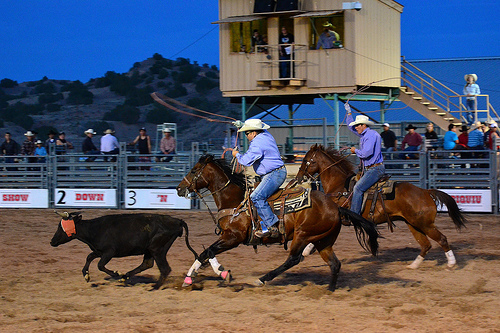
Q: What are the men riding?
A: Horses.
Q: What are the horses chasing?
A: A cow.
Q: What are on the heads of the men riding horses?
A: Cowboy hats.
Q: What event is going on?
A: Rodeo.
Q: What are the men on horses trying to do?
A: Rope a cow.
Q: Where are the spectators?
A: Behind the fence.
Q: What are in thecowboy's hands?
A: Lassoes.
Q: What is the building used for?
A: Announcing the action.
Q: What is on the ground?
A: Dirt.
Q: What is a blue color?
A: The sky.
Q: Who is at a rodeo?
A: Spectators.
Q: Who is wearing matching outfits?
A: Two men.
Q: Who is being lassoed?
A: A small calf.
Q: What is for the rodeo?
A: A viewing box.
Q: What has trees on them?
A: Mountains.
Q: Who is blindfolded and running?
A: A black bull.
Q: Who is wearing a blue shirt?
A: A man.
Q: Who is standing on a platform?
A: A woman.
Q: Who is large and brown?
A: A horse.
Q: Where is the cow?
A: In front of the horses.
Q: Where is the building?
A: On top of the stais.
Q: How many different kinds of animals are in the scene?
A: Two.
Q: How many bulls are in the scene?
A: One.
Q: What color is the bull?
A: Black.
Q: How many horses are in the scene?
A: Two.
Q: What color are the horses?
A: Brown.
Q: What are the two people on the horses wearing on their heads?
A: Cowboy hats.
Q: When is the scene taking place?
A: Evening.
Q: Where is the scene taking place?
A: At a rodeo.